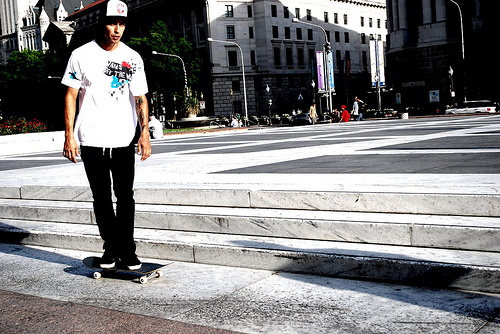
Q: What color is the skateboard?
A: Black.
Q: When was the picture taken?
A: Daytime.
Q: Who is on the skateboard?
A: The man in the foreground.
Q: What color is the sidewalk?
A: Gray.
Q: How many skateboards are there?
A: One.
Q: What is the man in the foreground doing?
A: Skateboarding.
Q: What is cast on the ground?
A: Shadows.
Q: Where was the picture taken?
A: On the street.